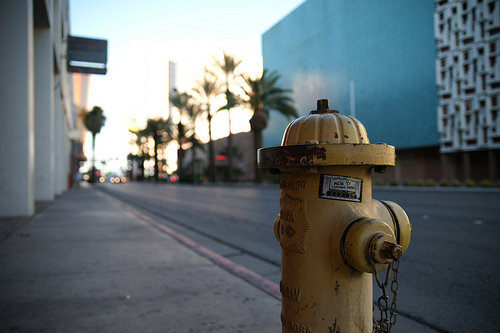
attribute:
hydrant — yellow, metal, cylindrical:
[255, 97, 412, 331]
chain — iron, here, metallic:
[367, 256, 401, 332]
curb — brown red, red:
[94, 188, 279, 321]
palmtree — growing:
[237, 66, 300, 186]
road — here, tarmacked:
[87, 174, 496, 329]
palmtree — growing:
[210, 50, 247, 185]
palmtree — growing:
[193, 66, 223, 180]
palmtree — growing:
[185, 101, 206, 183]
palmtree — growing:
[169, 84, 193, 183]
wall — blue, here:
[253, 0, 441, 157]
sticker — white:
[320, 172, 364, 203]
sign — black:
[66, 31, 111, 75]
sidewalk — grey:
[1, 184, 283, 333]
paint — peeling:
[257, 106, 397, 194]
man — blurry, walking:
[74, 168, 82, 192]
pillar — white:
[0, 0, 36, 220]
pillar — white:
[37, 17, 52, 209]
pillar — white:
[57, 99, 67, 194]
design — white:
[435, 0, 500, 160]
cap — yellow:
[255, 98, 397, 168]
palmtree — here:
[84, 104, 107, 187]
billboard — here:
[163, 58, 207, 128]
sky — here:
[69, 1, 304, 176]